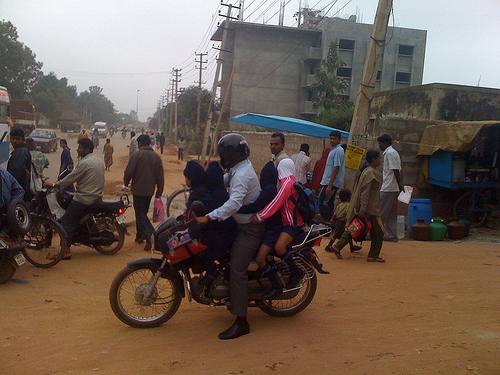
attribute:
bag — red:
[344, 219, 370, 243]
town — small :
[5, 2, 484, 364]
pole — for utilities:
[169, 69, 184, 153]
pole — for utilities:
[194, 53, 206, 148]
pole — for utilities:
[205, 42, 220, 170]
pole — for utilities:
[343, 0, 398, 216]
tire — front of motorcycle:
[96, 240, 190, 332]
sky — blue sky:
[83, 37, 164, 77]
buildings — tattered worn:
[388, 41, 420, 94]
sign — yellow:
[338, 137, 365, 175]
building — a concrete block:
[206, 7, 436, 200]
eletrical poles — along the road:
[134, 2, 444, 233]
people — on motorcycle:
[14, 115, 349, 350]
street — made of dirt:
[23, 109, 483, 352]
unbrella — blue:
[224, 101, 352, 142]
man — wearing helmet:
[209, 117, 256, 179]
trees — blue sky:
[337, 201, 374, 248]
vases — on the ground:
[405, 203, 475, 248]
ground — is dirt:
[377, 253, 475, 350]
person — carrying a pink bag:
[142, 173, 177, 243]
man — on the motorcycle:
[26, 130, 129, 267]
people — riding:
[164, 150, 289, 240]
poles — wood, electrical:
[121, 50, 313, 164]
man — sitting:
[67, 141, 126, 192]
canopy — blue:
[224, 95, 363, 150]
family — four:
[166, 133, 311, 245]